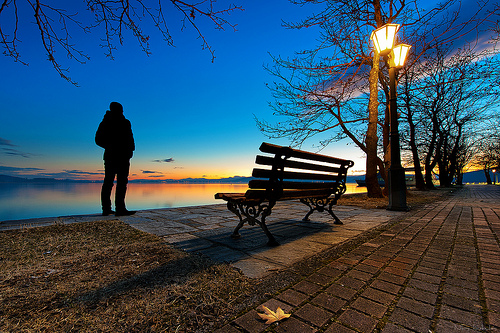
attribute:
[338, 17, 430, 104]
lamps —  yellow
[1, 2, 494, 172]
sky — blue, yellow, and orange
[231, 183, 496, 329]
walkway — bricks